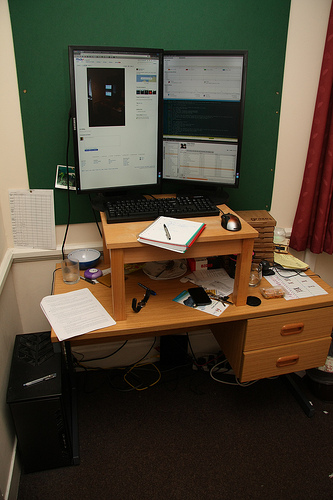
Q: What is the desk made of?
A: Wood.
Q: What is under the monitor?
A: Keyboard.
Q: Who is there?
A: No one.